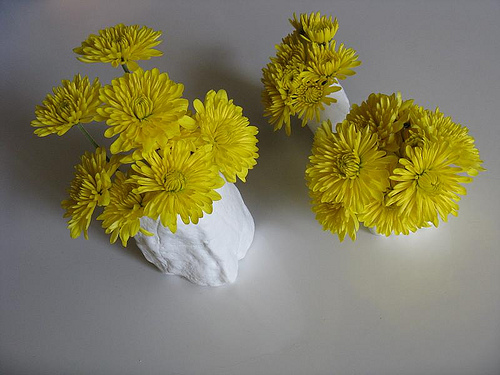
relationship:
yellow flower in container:
[65, 20, 166, 70] [133, 171, 256, 287]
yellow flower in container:
[28, 72, 115, 147] [133, 171, 256, 287]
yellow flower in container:
[58, 138, 113, 242] [133, 171, 256, 287]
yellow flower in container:
[132, 137, 224, 244] [133, 171, 256, 287]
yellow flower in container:
[90, 66, 194, 156] [133, 171, 256, 287]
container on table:
[133, 171, 256, 287] [4, 4, 498, 372]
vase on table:
[265, 30, 365, 111] [4, 4, 498, 372]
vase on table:
[341, 134, 495, 294] [4, 4, 498, 372]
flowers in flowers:
[31, 24, 259, 248] [31, 24, 259, 248]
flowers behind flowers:
[250, 5, 360, 135] [279, 65, 475, 208]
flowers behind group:
[20, 2, 483, 262] [52, 26, 461, 240]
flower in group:
[302, 93, 487, 245] [305, 88, 489, 242]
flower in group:
[387, 142, 467, 222] [305, 88, 489, 242]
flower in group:
[289, 70, 339, 125] [259, 9, 360, 126]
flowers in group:
[31, 24, 259, 248] [37, 22, 254, 290]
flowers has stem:
[31, 24, 259, 248] [71, 122, 121, 173]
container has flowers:
[133, 171, 256, 287] [96, 67, 183, 150]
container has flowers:
[133, 171, 256, 287] [173, 90, 259, 181]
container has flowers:
[133, 171, 256, 287] [61, 147, 116, 237]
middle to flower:
[125, 90, 157, 115] [81, 52, 251, 202]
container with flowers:
[133, 171, 256, 287] [31, 14, 480, 289]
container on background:
[133, 171, 256, 287] [13, 288, 493, 371]